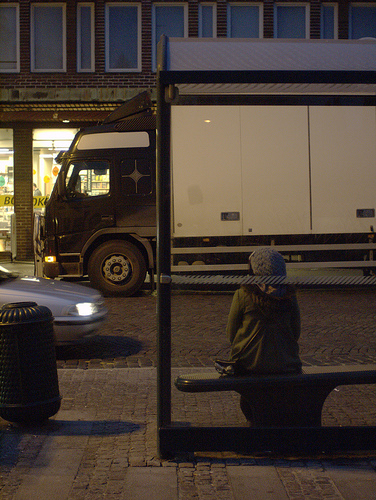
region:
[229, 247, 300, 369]
A woman on a bench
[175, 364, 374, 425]
A bench below the woman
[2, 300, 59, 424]
A trash can on the sidewalk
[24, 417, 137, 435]
A shadow on the ground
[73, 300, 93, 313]
A headlight on the car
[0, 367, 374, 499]
The sidewalk below the bench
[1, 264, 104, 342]
A car on the street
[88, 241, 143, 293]
The front tire of the truck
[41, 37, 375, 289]
A truck by the building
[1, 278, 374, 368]
The road beneath the car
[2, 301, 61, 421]
a black trash can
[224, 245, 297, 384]
a person sitting on a bench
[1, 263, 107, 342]
the silver car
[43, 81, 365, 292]
a semi truck on the street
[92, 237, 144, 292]
a black tire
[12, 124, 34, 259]
bricks on the building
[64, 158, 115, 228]
the door of the truck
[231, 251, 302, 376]
a person wearing a green coat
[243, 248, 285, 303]
a person wearing a grey hat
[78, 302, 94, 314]
the headlight of the car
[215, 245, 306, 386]
the women sitting on the bench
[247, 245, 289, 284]
the cap on the womens head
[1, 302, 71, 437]
the trashcan on the sidewalk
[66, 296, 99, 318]
the headlight on the front of the car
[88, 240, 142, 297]
the front tire of the truck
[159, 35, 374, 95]
the glass top of the canopy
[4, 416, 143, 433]
the trashcan on the sidewalk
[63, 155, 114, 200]
the window on the door of the truck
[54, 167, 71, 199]
the sideview mirror of the truck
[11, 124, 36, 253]
the brick column of the building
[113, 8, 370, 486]
person sitting on bench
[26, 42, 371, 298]
large truck on street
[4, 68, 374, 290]
truck is black and white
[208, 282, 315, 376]
person wearing green top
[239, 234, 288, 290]
person wearing grey hat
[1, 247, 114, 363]
silver car on street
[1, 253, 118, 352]
car headlights turned on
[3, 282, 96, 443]
black trash can on sidewalk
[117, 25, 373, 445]
white shelter over bench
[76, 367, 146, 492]
patchwork pattern on sidewalk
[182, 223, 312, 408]
a woman is sitting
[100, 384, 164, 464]
a gray stone floor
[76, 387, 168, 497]
a gray stone floor